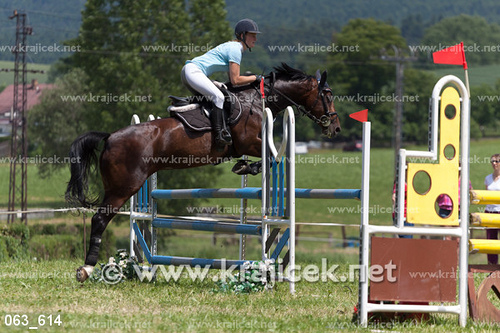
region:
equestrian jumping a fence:
[70, 15, 351, 280]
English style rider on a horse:
[160, 19, 283, 144]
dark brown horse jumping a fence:
[66, 70, 348, 282]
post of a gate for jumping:
[153, 180, 362, 227]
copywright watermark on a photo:
[97, 250, 401, 297]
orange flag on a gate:
[425, 33, 473, 79]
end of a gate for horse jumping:
[354, 88, 471, 330]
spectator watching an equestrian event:
[475, 153, 497, 198]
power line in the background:
[2, 16, 63, 240]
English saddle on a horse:
[170, 88, 243, 133]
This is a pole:
[350, 109, 388, 328]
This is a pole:
[461, 76, 481, 330]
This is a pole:
[281, 97, 318, 294]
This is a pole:
[257, 106, 275, 290]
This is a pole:
[149, 128, 163, 296]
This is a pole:
[383, 40, 415, 268]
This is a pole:
[4, 18, 51, 280]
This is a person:
[170, 15, 262, 127]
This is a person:
[475, 136, 495, 276]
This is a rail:
[144, 177, 389, 229]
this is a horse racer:
[178, 11, 273, 125]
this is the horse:
[135, 118, 175, 168]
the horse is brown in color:
[145, 123, 174, 153]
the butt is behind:
[180, 63, 209, 85]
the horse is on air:
[232, 96, 294, 181]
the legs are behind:
[75, 205, 123, 285]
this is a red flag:
[423, 45, 469, 67]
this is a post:
[174, 180, 259, 272]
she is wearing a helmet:
[238, 22, 260, 30]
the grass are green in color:
[237, 284, 294, 331]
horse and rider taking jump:
[68, 23, 335, 281]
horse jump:
[357, 41, 499, 331]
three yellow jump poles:
[466, 187, 498, 251]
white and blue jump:
[118, 109, 360, 282]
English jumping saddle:
[165, 81, 241, 131]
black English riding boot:
[211, 104, 233, 148]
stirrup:
[218, 109, 233, 144]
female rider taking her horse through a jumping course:
[4, 1, 498, 326]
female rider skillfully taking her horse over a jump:
[59, 17, 341, 292]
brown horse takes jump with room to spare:
[70, 15, 337, 292]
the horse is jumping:
[47, 15, 373, 241]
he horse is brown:
[42, 17, 352, 222]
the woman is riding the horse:
[161, 5, 289, 153]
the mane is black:
[251, 49, 313, 95]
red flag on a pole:
[337, 92, 378, 154]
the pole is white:
[341, 106, 376, 327]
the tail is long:
[42, 118, 122, 204]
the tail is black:
[44, 113, 134, 205]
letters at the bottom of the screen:
[115, 241, 408, 303]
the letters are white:
[110, 243, 412, 304]